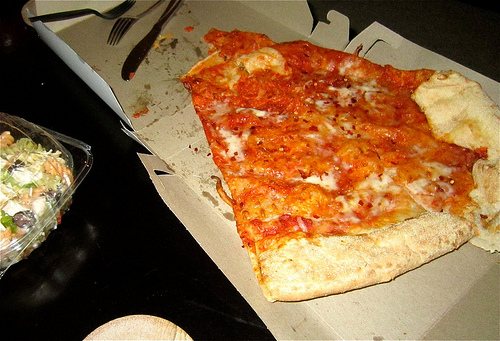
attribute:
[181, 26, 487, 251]
cheese — white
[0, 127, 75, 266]
salad — small, mixed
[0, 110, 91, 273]
container — small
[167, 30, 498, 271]
pizza — cheese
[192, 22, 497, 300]
pizza — bitten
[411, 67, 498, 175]
crust — folded over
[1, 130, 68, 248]
salad — package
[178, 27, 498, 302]
slice — large, pizza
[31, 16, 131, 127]
trim — white